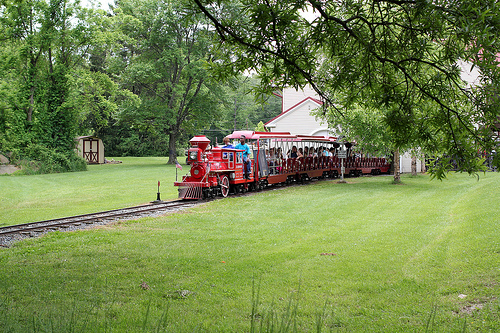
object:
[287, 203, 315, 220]
grass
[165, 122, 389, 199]
train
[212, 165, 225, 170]
red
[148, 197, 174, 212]
tracks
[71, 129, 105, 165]
shed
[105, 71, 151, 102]
distance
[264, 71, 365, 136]
building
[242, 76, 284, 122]
background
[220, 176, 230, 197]
wheel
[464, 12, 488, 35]
leaves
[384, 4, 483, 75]
tree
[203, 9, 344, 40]
branch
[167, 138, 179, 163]
trunk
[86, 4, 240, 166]
tree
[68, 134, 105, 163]
barn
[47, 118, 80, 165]
bushes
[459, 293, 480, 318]
cut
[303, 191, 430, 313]
lawn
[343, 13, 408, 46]
branches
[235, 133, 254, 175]
conductor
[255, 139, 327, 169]
people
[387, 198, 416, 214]
green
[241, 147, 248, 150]
blue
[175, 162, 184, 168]
flag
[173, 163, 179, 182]
pole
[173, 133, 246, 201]
engine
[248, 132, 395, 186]
cars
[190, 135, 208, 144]
smoke stack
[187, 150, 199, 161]
head light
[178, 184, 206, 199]
cowcatcher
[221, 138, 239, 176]
engineers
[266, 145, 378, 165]
passengers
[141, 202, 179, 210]
guage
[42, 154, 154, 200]
yard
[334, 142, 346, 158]
sign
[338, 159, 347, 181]
pole